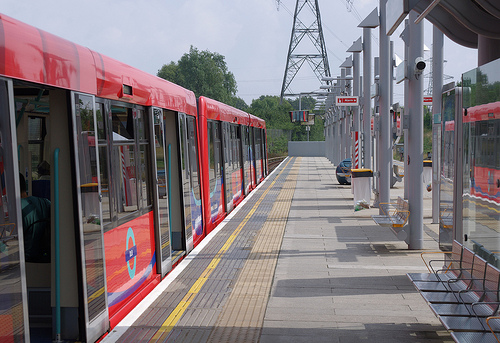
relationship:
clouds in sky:
[121, 21, 286, 43] [0, 3, 482, 115]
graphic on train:
[120, 226, 145, 275] [2, 18, 275, 337]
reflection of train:
[428, 50, 498, 262] [12, 19, 284, 204]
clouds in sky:
[0, 0, 479, 110] [28, 0, 428, 98]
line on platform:
[148, 157, 293, 342] [101, 154, 445, 341]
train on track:
[2, 18, 275, 337] [86, 152, 285, 342]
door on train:
[7, 79, 77, 342] [2, 18, 275, 337]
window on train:
[6, 90, 271, 332] [2, 18, 275, 337]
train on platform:
[2, 18, 275, 337] [101, 154, 445, 341]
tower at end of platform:
[283, 1, 346, 116] [101, 154, 445, 341]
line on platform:
[148, 157, 293, 342] [96, 156, 499, 341]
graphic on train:
[123, 226, 137, 279] [2, 18, 275, 337]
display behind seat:
[434, 79, 464, 259] [406, 236, 462, 285]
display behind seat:
[434, 79, 464, 259] [412, 245, 472, 292]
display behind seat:
[434, 79, 464, 259] [430, 251, 486, 317]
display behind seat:
[434, 79, 464, 259] [430, 261, 497, 315]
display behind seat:
[434, 79, 464, 259] [438, 315, 498, 326]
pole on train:
[47, 145, 62, 342] [2, 18, 275, 337]